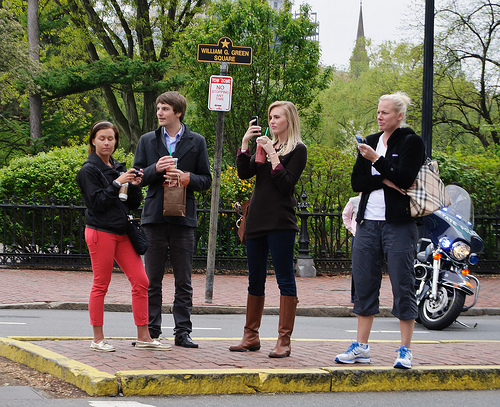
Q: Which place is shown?
A: It is a sidewalk.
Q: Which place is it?
A: It is a sidewalk.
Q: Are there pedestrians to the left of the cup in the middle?
A: Yes, there is a pedestrian to the left of the cup.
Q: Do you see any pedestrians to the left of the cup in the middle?
A: Yes, there is a pedestrian to the left of the cup.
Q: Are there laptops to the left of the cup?
A: No, there is a pedestrian to the left of the cup.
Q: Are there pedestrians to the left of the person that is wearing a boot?
A: Yes, there is a pedestrian to the left of the person.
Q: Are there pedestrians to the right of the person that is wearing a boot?
A: No, the pedestrian is to the left of the person.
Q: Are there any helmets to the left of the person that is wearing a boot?
A: No, there is a pedestrian to the left of the person.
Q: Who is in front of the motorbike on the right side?
A: The pedestrian is in front of the motorbike.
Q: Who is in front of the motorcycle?
A: The pedestrian is in front of the motorbike.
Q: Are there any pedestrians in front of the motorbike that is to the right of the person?
A: Yes, there is a pedestrian in front of the motorbike.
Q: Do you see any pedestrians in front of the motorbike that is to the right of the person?
A: Yes, there is a pedestrian in front of the motorbike.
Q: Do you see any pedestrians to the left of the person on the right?
A: Yes, there is a pedestrian to the left of the person.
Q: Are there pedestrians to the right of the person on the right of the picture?
A: No, the pedestrian is to the left of the person.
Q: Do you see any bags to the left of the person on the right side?
A: No, there is a pedestrian to the left of the person.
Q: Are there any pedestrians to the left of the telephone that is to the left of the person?
A: Yes, there is a pedestrian to the left of the phone.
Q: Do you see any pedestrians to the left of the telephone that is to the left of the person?
A: Yes, there is a pedestrian to the left of the phone.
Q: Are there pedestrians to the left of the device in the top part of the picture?
A: Yes, there is a pedestrian to the left of the phone.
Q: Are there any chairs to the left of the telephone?
A: No, there is a pedestrian to the left of the telephone.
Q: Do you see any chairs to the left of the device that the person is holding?
A: No, there is a pedestrian to the left of the telephone.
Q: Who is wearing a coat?
A: The pedestrian is wearing a coat.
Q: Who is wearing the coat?
A: The pedestrian is wearing a coat.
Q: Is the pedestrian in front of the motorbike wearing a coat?
A: Yes, the pedestrian is wearing a coat.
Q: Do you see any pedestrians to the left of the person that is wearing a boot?
A: Yes, there is a pedestrian to the left of the person.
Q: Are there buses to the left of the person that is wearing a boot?
A: No, there is a pedestrian to the left of the person.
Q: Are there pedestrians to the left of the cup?
A: Yes, there is a pedestrian to the left of the cup.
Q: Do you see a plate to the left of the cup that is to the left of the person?
A: No, there is a pedestrian to the left of the cup.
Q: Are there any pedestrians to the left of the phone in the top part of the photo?
A: Yes, there is a pedestrian to the left of the phone.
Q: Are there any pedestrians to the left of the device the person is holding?
A: Yes, there is a pedestrian to the left of the phone.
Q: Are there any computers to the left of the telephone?
A: No, there is a pedestrian to the left of the telephone.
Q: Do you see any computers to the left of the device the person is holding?
A: No, there is a pedestrian to the left of the telephone.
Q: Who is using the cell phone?
A: The pedestrian is using the cell phone.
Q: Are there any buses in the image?
A: No, there are no buses.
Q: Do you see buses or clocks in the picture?
A: No, there are no buses or clocks.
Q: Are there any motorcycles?
A: Yes, there is a motorcycle.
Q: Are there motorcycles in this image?
A: Yes, there is a motorcycle.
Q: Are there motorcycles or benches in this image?
A: Yes, there is a motorcycle.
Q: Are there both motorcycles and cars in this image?
A: No, there is a motorcycle but no cars.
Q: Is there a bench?
A: No, there are no benches.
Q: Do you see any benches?
A: No, there are no benches.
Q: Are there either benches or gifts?
A: No, there are no benches or gifts.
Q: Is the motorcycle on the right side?
A: Yes, the motorcycle is on the right of the image.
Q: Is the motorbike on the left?
A: No, the motorbike is on the right of the image.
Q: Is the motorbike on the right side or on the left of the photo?
A: The motorbike is on the right of the image.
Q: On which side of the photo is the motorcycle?
A: The motorcycle is on the right of the image.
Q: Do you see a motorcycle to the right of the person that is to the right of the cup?
A: Yes, there is a motorcycle to the right of the person.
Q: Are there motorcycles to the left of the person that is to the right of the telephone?
A: No, the motorcycle is to the right of the person.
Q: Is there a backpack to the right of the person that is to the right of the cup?
A: No, there is a motorcycle to the right of the person.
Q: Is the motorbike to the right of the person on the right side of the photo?
A: Yes, the motorbike is to the right of the person.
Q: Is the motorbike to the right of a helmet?
A: No, the motorbike is to the right of the person.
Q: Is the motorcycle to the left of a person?
A: No, the motorcycle is to the right of a person.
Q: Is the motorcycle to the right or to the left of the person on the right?
A: The motorcycle is to the right of the person.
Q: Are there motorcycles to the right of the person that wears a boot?
A: Yes, there is a motorcycle to the right of the person.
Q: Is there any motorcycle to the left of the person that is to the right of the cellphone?
A: No, the motorcycle is to the right of the person.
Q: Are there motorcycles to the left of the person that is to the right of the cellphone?
A: No, the motorcycle is to the right of the person.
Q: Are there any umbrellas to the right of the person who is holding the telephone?
A: No, there is a motorcycle to the right of the person.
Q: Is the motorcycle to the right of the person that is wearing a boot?
A: Yes, the motorcycle is to the right of the person.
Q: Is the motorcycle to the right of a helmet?
A: No, the motorcycle is to the right of the person.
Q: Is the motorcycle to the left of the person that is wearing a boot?
A: No, the motorcycle is to the right of the person.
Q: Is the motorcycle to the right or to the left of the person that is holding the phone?
A: The motorcycle is to the right of the person.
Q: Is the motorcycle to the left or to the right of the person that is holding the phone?
A: The motorcycle is to the right of the person.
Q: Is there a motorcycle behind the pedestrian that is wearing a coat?
A: Yes, there is a motorcycle behind the pedestrian.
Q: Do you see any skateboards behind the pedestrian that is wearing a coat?
A: No, there is a motorcycle behind the pedestrian.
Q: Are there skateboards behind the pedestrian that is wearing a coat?
A: No, there is a motorcycle behind the pedestrian.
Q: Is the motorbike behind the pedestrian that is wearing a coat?
A: Yes, the motorbike is behind the pedestrian.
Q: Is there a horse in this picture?
A: No, there are no horses.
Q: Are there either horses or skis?
A: No, there are no horses or skis.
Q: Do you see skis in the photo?
A: No, there are no skis.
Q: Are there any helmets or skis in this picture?
A: No, there are no skis or helmets.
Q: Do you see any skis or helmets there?
A: No, there are no skis or helmets.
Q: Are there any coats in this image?
A: Yes, there is a coat.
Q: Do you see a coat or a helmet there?
A: Yes, there is a coat.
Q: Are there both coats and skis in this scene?
A: No, there is a coat but no skis.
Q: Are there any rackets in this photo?
A: No, there are no rackets.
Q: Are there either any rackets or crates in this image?
A: No, there are no rackets or crates.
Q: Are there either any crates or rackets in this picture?
A: No, there are no rackets or crates.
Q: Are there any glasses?
A: No, there are no glasses.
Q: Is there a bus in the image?
A: No, there are no buses.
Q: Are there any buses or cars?
A: No, there are no buses or cars.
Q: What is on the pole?
A: The sign is on the pole.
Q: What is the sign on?
A: The sign is on the pole.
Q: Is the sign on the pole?
A: Yes, the sign is on the pole.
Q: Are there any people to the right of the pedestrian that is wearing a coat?
A: Yes, there is a person to the right of the pedestrian.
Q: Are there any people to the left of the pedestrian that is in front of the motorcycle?
A: No, the person is to the right of the pedestrian.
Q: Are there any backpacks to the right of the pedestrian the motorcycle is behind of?
A: No, there is a person to the right of the pedestrian.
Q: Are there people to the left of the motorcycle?
A: Yes, there is a person to the left of the motorcycle.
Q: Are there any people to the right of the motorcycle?
A: No, the person is to the left of the motorcycle.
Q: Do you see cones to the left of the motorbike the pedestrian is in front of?
A: No, there is a person to the left of the motorbike.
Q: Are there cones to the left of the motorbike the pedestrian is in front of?
A: No, there is a person to the left of the motorbike.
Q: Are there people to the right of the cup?
A: Yes, there is a person to the right of the cup.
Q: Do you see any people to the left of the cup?
A: No, the person is to the right of the cup.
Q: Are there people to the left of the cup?
A: No, the person is to the right of the cup.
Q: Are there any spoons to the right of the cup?
A: No, there is a person to the right of the cup.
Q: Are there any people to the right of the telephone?
A: Yes, there is a person to the right of the telephone.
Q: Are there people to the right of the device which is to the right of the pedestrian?
A: Yes, there is a person to the right of the telephone.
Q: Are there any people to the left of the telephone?
A: No, the person is to the right of the telephone.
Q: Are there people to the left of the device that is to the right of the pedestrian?
A: No, the person is to the right of the telephone.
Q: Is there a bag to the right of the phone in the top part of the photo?
A: No, there is a person to the right of the telephone.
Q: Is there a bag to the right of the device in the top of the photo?
A: No, there is a person to the right of the telephone.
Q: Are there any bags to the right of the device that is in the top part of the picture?
A: No, there is a person to the right of the telephone.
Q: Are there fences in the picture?
A: Yes, there is a fence.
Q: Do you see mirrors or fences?
A: Yes, there is a fence.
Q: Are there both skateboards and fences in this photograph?
A: No, there is a fence but no skateboards.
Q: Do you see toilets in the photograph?
A: No, there are no toilets.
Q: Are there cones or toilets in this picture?
A: No, there are no toilets or cones.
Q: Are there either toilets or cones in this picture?
A: No, there are no toilets or cones.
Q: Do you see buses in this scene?
A: No, there are no buses.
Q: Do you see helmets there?
A: No, there are no helmets.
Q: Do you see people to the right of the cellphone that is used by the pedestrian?
A: Yes, there is a person to the right of the cell phone.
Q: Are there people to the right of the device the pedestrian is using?
A: Yes, there is a person to the right of the cell phone.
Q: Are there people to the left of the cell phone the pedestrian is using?
A: No, the person is to the right of the cellphone.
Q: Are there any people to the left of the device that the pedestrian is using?
A: No, the person is to the right of the cellphone.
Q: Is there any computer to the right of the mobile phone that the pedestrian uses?
A: No, there is a person to the right of the cellphone.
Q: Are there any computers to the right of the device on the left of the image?
A: No, there is a person to the right of the cellphone.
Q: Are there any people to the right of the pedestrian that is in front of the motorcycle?
A: Yes, there is a person to the right of the pedestrian.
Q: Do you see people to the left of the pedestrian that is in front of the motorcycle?
A: No, the person is to the right of the pedestrian.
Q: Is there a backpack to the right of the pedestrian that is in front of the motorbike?
A: No, there is a person to the right of the pedestrian.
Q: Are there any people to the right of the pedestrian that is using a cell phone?
A: Yes, there is a person to the right of the pedestrian.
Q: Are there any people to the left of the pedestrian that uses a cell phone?
A: No, the person is to the right of the pedestrian.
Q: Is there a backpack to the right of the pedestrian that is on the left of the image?
A: No, there is a person to the right of the pedestrian.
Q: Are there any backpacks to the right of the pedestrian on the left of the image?
A: No, there is a person to the right of the pedestrian.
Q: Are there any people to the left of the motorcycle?
A: Yes, there is a person to the left of the motorcycle.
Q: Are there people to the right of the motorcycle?
A: No, the person is to the left of the motorcycle.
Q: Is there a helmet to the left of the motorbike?
A: No, there is a person to the left of the motorbike.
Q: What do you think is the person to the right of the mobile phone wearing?
A: The person is wearing a boot.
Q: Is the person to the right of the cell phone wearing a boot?
A: Yes, the person is wearing a boot.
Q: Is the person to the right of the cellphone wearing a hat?
A: No, the person is wearing a boot.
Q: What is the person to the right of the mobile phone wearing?
A: The person is wearing a boot.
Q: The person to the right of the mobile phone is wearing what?
A: The person is wearing a boot.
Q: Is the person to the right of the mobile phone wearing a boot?
A: Yes, the person is wearing a boot.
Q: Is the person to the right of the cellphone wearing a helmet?
A: No, the person is wearing a boot.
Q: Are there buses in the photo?
A: No, there are no buses.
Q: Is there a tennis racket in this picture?
A: No, there are no rackets.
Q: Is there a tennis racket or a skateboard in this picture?
A: No, there are no rackets or skateboards.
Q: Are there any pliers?
A: No, there are no pliers.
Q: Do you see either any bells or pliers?
A: No, there are no pliers or bells.